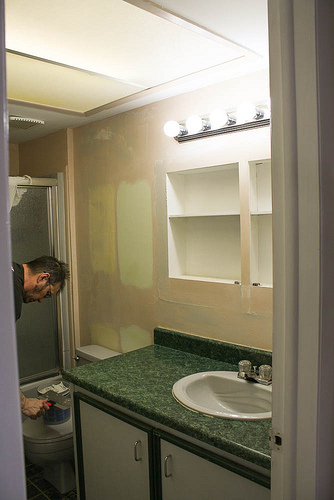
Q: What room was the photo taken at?
A: It was taken at the bathroom.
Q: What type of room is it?
A: It is a bathroom.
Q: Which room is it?
A: It is a bathroom.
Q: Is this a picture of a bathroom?
A: Yes, it is showing a bathroom.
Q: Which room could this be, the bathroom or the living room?
A: It is the bathroom.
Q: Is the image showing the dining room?
A: No, the picture is showing the bathroom.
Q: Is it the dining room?
A: No, it is the bathroom.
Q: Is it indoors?
A: Yes, it is indoors.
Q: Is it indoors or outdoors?
A: It is indoors.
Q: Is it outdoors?
A: No, it is indoors.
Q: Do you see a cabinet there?
A: Yes, there is a cabinet.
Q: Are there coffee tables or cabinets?
A: Yes, there is a cabinet.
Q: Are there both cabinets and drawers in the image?
A: No, there is a cabinet but no drawers.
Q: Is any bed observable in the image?
A: No, there are no beds.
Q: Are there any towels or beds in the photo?
A: No, there are no beds or towels.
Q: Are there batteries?
A: No, there are no batteries.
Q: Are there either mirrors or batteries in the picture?
A: No, there are no batteries or mirrors.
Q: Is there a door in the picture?
A: Yes, there is a door.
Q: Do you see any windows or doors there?
A: Yes, there is a door.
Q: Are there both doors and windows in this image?
A: No, there is a door but no windows.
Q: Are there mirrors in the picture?
A: No, there are no mirrors.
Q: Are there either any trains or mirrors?
A: No, there are no mirrors or trains.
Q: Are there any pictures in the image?
A: No, there are no pictures.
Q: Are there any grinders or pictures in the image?
A: No, there are no pictures or grinders.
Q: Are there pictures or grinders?
A: No, there are no pictures or grinders.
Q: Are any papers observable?
A: No, there are no papers.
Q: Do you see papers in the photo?
A: No, there are no papers.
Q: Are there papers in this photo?
A: No, there are no papers.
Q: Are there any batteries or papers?
A: No, there are no papers or batteries.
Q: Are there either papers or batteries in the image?
A: No, there are no papers or batteries.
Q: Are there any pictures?
A: No, there are no pictures.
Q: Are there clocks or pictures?
A: No, there are no pictures or clocks.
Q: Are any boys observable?
A: No, there are no boys.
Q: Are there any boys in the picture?
A: No, there are no boys.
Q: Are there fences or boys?
A: No, there are no boys or fences.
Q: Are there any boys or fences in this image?
A: No, there are no boys or fences.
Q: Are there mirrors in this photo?
A: No, there are no mirrors.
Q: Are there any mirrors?
A: No, there are no mirrors.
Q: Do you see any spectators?
A: No, there are no spectators.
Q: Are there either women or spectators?
A: No, there are no spectators or women.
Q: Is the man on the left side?
A: Yes, the man is on the left of the image.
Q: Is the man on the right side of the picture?
A: No, the man is on the left of the image.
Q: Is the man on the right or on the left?
A: The man is on the left of the image.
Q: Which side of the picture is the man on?
A: The man is on the left of the image.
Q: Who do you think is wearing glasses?
A: The man is wearing glasses.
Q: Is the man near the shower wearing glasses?
A: Yes, the man is wearing glasses.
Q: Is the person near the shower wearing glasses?
A: Yes, the man is wearing glasses.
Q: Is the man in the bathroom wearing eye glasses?
A: No, the man is wearing glasses.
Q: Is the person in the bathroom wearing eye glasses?
A: No, the man is wearing glasses.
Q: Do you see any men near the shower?
A: Yes, there is a man near the shower.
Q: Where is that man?
A: The man is in the bathroom.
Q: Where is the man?
A: The man is in the bathroom.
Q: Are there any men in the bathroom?
A: Yes, there is a man in the bathroom.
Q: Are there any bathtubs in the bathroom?
A: No, there is a man in the bathroom.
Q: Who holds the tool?
A: The man holds the tool.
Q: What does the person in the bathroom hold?
A: The man holds the tool.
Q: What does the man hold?
A: The man holds the tool.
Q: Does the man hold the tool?
A: Yes, the man holds the tool.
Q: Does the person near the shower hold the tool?
A: Yes, the man holds the tool.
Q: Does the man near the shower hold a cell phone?
A: No, the man holds the tool.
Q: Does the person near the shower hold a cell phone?
A: No, the man holds the tool.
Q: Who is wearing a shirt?
A: The man is wearing a shirt.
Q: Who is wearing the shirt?
A: The man is wearing a shirt.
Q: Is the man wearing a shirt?
A: Yes, the man is wearing a shirt.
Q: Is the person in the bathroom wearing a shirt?
A: Yes, the man is wearing a shirt.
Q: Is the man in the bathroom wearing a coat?
A: No, the man is wearing a shirt.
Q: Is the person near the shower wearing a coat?
A: No, the man is wearing a shirt.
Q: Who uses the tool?
A: The man uses the tool.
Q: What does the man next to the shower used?
A: The man uses a tool.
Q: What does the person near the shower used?
A: The man uses a tool.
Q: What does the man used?
A: The man uses a tool.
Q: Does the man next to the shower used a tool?
A: Yes, the man uses a tool.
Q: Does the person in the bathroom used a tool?
A: Yes, the man uses a tool.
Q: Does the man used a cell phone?
A: No, the man uses a tool.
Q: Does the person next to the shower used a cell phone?
A: No, the man uses a tool.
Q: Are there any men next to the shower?
A: Yes, there is a man next to the shower.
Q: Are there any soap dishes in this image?
A: No, there are no soap dishes.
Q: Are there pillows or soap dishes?
A: No, there are no soap dishes or pillows.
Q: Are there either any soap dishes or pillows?
A: No, there are no soap dishes or pillows.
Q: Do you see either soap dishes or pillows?
A: No, there are no soap dishes or pillows.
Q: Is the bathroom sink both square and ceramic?
A: No, the sink is ceramic but round.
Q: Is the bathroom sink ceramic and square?
A: No, the sink is ceramic but round.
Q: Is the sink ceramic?
A: Yes, the sink is ceramic.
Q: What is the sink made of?
A: The sink is made of porcelain.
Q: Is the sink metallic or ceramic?
A: The sink is ceramic.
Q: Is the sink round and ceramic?
A: Yes, the sink is round and ceramic.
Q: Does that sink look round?
A: Yes, the sink is round.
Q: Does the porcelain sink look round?
A: Yes, the sink is round.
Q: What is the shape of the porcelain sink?
A: The sink is round.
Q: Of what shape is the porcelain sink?
A: The sink is round.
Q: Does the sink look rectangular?
A: No, the sink is round.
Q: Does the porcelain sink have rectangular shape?
A: No, the sink is round.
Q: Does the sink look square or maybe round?
A: The sink is round.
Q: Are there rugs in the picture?
A: No, there are no rugs.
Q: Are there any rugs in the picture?
A: No, there are no rugs.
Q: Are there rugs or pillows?
A: No, there are no rugs or pillows.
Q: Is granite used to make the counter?
A: Yes, the counter is made of granite.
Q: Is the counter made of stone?
A: No, the counter is made of granite.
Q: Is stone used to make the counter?
A: No, the counter is made of granite.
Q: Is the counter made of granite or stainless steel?
A: The counter is made of granite.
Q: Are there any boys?
A: No, there are no boys.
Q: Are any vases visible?
A: No, there are no vases.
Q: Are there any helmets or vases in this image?
A: No, there are no vases or helmets.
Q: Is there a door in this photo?
A: Yes, there is a door.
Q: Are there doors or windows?
A: Yes, there is a door.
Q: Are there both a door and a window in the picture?
A: No, there is a door but no windows.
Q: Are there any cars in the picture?
A: No, there are no cars.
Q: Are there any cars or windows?
A: No, there are no cars or windows.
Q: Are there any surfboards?
A: No, there are no surfboards.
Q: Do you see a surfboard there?
A: No, there are no surfboards.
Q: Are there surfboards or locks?
A: No, there are no surfboards or locks.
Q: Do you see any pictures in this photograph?
A: No, there are no pictures.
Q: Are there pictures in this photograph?
A: No, there are no pictures.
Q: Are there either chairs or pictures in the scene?
A: No, there are no pictures or chairs.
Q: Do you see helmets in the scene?
A: No, there are no helmets.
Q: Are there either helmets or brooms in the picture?
A: No, there are no helmets or brooms.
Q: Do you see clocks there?
A: No, there are no clocks.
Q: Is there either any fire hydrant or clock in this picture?
A: No, there are no clocks or fire hydrants.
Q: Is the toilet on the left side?
A: Yes, the toilet is on the left of the image.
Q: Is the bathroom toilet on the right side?
A: No, the toilet is on the left of the image.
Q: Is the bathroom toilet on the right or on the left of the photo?
A: The toilet is on the left of the image.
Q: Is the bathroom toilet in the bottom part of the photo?
A: Yes, the toilet is in the bottom of the image.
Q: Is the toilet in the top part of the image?
A: No, the toilet is in the bottom of the image.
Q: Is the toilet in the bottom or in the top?
A: The toilet is in the bottom of the image.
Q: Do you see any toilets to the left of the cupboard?
A: Yes, there is a toilet to the left of the cupboard.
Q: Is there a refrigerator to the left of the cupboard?
A: No, there is a toilet to the left of the cupboard.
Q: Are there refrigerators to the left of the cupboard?
A: No, there is a toilet to the left of the cupboard.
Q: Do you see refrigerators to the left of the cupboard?
A: No, there is a toilet to the left of the cupboard.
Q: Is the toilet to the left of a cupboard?
A: Yes, the toilet is to the left of a cupboard.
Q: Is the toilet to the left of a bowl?
A: No, the toilet is to the left of a cupboard.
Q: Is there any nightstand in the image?
A: No, there are no nightstands.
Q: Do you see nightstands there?
A: No, there are no nightstands.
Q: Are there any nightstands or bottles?
A: No, there are no nightstands or bottles.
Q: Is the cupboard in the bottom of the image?
A: Yes, the cupboard is in the bottom of the image.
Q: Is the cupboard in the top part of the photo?
A: No, the cupboard is in the bottom of the image.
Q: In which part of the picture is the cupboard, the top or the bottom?
A: The cupboard is in the bottom of the image.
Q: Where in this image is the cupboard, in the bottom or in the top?
A: The cupboard is in the bottom of the image.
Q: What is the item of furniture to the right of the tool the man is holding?
A: The piece of furniture is a cupboard.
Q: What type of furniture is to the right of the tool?
A: The piece of furniture is a cupboard.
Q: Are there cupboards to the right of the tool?
A: Yes, there is a cupboard to the right of the tool.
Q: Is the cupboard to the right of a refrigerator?
A: No, the cupboard is to the right of a tool.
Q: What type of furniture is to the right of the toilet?
A: The piece of furniture is a cupboard.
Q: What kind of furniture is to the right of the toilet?
A: The piece of furniture is a cupboard.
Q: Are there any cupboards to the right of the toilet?
A: Yes, there is a cupboard to the right of the toilet.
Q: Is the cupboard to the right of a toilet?
A: Yes, the cupboard is to the right of a toilet.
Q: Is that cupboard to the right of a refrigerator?
A: No, the cupboard is to the right of a toilet.